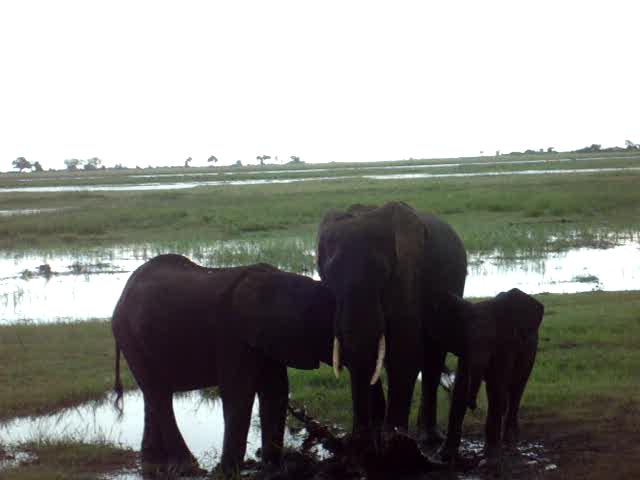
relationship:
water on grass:
[2, 241, 638, 322] [0, 153, 637, 478]